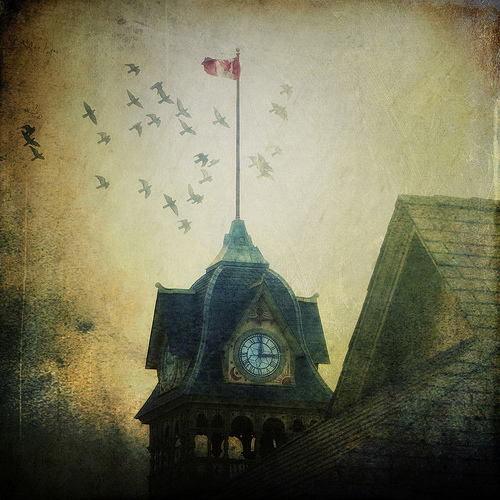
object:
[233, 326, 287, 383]
clock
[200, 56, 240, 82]
flag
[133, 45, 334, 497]
tower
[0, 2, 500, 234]
part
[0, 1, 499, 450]
sky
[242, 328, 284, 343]
edge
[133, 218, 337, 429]
part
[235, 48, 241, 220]
pole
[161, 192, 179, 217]
bird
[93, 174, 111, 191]
bird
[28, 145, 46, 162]
bird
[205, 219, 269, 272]
roof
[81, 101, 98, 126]
bird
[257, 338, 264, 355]
hands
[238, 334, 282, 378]
face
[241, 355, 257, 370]
numbers